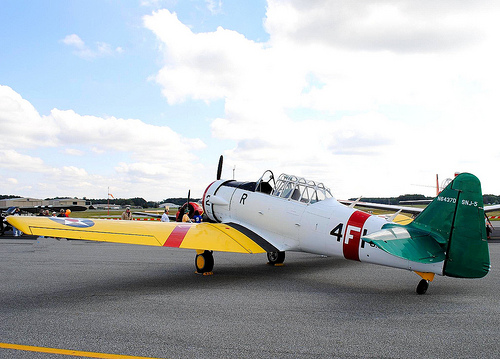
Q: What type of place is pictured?
A: It is a runway.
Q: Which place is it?
A: It is a runway.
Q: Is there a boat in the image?
A: No, there are no boats.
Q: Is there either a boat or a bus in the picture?
A: No, there are no boats or buses.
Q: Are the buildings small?
A: Yes, the buildings are small.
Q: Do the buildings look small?
A: Yes, the buildings are small.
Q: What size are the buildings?
A: The buildings are small.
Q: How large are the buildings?
A: The buildings are small.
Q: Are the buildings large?
A: No, the buildings are small.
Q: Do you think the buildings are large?
A: No, the buildings are small.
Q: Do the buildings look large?
A: No, the buildings are small.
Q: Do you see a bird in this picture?
A: No, there are no birds.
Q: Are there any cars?
A: No, there are no cars.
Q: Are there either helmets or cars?
A: No, there are no cars or helmets.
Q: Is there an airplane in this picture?
A: Yes, there is an airplane.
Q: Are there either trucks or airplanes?
A: Yes, there is an airplane.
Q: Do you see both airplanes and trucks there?
A: No, there is an airplane but no trucks.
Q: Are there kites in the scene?
A: No, there are no kites.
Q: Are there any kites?
A: No, there are no kites.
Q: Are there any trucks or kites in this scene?
A: No, there are no kites or trucks.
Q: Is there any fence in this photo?
A: No, there are no fences.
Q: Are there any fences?
A: No, there are no fences.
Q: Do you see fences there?
A: No, there are no fences.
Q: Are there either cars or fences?
A: No, there are no fences or cars.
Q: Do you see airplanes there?
A: Yes, there is an airplane.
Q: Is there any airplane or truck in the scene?
A: Yes, there is an airplane.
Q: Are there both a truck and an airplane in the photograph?
A: No, there is an airplane but no trucks.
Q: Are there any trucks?
A: No, there are no trucks.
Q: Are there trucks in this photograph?
A: No, there are no trucks.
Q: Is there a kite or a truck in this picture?
A: No, there are no trucks or kites.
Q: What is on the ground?
A: The airplane is on the ground.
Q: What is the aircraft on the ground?
A: The aircraft is an airplane.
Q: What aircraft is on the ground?
A: The aircraft is an airplane.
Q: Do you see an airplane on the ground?
A: Yes, there is an airplane on the ground.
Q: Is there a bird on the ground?
A: No, there is an airplane on the ground.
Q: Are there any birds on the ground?
A: No, there is an airplane on the ground.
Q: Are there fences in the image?
A: No, there are no fences.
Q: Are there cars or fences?
A: No, there are no fences or cars.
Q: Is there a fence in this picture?
A: No, there are no fences.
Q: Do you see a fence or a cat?
A: No, there are no fences or cats.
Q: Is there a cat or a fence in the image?
A: No, there are no fences or cats.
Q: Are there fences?
A: No, there are no fences.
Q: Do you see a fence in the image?
A: No, there are no fences.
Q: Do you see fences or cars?
A: No, there are no fences or cars.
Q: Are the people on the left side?
A: Yes, the people are on the left of the image.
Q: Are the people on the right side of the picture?
A: No, the people are on the left of the image.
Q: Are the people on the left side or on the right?
A: The people are on the left of the image.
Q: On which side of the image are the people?
A: The people are on the left of the image.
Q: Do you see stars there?
A: Yes, there is a star.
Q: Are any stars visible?
A: Yes, there is a star.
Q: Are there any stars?
A: Yes, there is a star.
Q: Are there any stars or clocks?
A: Yes, there is a star.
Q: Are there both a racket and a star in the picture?
A: No, there is a star but no rackets.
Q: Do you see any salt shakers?
A: No, there are no salt shakers.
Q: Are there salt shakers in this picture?
A: No, there are no salt shakers.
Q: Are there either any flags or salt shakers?
A: No, there are no salt shakers or flags.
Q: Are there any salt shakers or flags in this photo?
A: No, there are no salt shakers or flags.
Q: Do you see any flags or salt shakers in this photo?
A: No, there are no salt shakers or flags.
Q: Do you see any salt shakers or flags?
A: No, there are no salt shakers or flags.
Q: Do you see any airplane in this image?
A: Yes, there is an airplane.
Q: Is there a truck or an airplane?
A: Yes, there is an airplane.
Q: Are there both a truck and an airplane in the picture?
A: No, there is an airplane but no trucks.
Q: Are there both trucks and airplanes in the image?
A: No, there is an airplane but no trucks.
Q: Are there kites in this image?
A: No, there are no kites.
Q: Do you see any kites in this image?
A: No, there are no kites.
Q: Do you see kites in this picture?
A: No, there are no kites.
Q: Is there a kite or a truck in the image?
A: No, there are no kites or trucks.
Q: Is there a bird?
A: No, there are no birds.